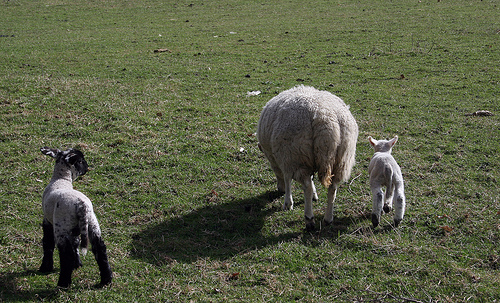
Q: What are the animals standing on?
A: Grass.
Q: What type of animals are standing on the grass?
A: Sheep.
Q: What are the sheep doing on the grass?
A: Standing.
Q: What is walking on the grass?
A: A young white sheep.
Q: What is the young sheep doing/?
A: Standing.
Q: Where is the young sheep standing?
A: In the field.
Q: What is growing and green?
A: Grass.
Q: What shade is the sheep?
A: White.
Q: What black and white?
A: The lamb.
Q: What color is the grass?
A: Green.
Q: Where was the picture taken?
A: In a field.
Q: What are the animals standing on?
A: The grass.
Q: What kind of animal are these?
A: Sheep.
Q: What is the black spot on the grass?
A: A shadow.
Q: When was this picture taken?
A: During the day.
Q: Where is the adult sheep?
A: Between the lambs.